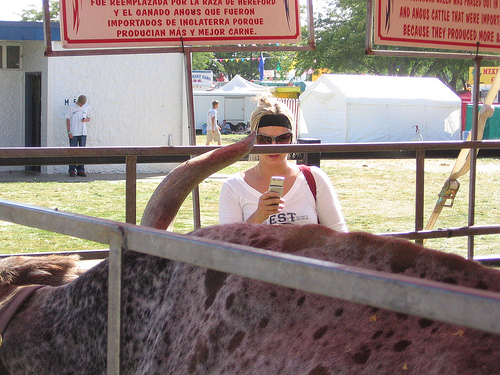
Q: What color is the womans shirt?
A: White.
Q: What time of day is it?
A: Daytime.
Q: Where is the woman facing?
A: Down.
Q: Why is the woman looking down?
A: Looking at phone.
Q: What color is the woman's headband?
A: Black.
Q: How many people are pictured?
A: Three.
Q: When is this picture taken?
A: Carnival.